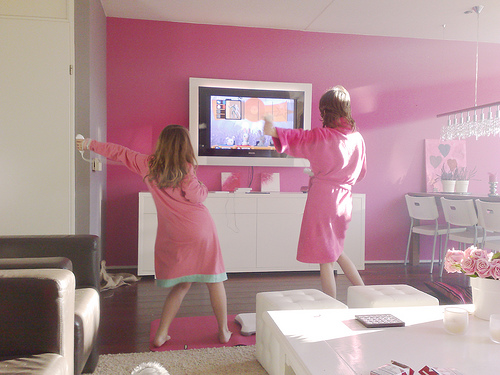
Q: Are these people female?
A: Yes, all the people are female.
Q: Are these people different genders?
A: No, all the people are female.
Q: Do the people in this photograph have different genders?
A: No, all the people are female.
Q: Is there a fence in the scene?
A: No, there are no fences.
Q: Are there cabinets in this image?
A: Yes, there is a cabinet.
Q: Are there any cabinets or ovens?
A: Yes, there is a cabinet.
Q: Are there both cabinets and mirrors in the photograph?
A: No, there is a cabinet but no mirrors.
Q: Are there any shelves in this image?
A: No, there are no shelves.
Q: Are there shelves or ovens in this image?
A: No, there are no shelves or ovens.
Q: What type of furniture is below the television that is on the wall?
A: The piece of furniture is a cabinet.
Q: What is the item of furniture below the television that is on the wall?
A: The piece of furniture is a cabinet.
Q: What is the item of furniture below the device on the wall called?
A: The piece of furniture is a cabinet.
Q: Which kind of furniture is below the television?
A: The piece of furniture is a cabinet.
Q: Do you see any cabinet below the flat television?
A: Yes, there is a cabinet below the television.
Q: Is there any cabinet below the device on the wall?
A: Yes, there is a cabinet below the television.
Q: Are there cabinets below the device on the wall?
A: Yes, there is a cabinet below the television.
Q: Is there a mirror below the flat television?
A: No, there is a cabinet below the TV.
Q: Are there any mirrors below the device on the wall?
A: No, there is a cabinet below the TV.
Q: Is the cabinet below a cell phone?
A: No, the cabinet is below a television.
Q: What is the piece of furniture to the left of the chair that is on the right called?
A: The piece of furniture is a cabinet.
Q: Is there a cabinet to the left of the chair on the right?
A: Yes, there is a cabinet to the left of the chair.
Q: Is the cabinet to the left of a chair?
A: Yes, the cabinet is to the left of a chair.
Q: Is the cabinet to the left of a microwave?
A: No, the cabinet is to the left of a chair.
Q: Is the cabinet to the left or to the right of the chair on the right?
A: The cabinet is to the left of the chair.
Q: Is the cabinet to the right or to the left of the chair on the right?
A: The cabinet is to the left of the chair.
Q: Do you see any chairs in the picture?
A: Yes, there is a chair.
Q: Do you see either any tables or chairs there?
A: Yes, there is a chair.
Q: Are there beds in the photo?
A: No, there are no beds.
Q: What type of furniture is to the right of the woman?
A: The piece of furniture is a chair.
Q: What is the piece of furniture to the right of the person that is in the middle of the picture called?
A: The piece of furniture is a chair.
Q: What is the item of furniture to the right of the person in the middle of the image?
A: The piece of furniture is a chair.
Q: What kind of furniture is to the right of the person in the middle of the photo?
A: The piece of furniture is a chair.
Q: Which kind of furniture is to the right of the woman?
A: The piece of furniture is a chair.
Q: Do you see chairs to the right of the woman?
A: Yes, there is a chair to the right of the woman.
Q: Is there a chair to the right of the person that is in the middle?
A: Yes, there is a chair to the right of the woman.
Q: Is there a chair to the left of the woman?
A: No, the chair is to the right of the woman.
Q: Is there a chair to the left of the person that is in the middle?
A: No, the chair is to the right of the woman.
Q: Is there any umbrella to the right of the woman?
A: No, there is a chair to the right of the woman.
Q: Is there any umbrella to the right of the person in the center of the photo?
A: No, there is a chair to the right of the woman.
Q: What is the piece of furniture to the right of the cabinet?
A: The piece of furniture is a chair.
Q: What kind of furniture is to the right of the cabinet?
A: The piece of furniture is a chair.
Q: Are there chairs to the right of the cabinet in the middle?
A: Yes, there is a chair to the right of the cabinet.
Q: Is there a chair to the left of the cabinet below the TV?
A: No, the chair is to the right of the cabinet.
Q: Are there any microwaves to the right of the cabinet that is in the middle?
A: No, there is a chair to the right of the cabinet.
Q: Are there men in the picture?
A: No, there are no men.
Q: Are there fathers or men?
A: No, there are no men or fathers.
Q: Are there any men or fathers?
A: No, there are no men or fathers.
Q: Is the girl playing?
A: Yes, the girl is playing.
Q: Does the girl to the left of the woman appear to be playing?
A: Yes, the girl is playing.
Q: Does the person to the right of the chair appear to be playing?
A: Yes, the girl is playing.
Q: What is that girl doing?
A: The girl is playing.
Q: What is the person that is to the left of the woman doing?
A: The girl is playing.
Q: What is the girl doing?
A: The girl is playing.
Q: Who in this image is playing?
A: The girl is playing.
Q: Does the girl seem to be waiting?
A: No, the girl is playing.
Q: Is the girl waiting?
A: No, the girl is playing.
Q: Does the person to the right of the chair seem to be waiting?
A: No, the girl is playing.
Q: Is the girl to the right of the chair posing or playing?
A: The girl is playing.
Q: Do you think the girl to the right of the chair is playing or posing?
A: The girl is playing.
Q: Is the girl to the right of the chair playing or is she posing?
A: The girl is playing.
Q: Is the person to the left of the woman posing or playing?
A: The girl is playing.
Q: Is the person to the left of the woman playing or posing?
A: The girl is playing.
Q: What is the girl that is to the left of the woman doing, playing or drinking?
A: The girl is playing.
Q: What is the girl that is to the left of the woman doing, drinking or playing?
A: The girl is playing.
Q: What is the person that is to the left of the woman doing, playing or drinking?
A: The girl is playing.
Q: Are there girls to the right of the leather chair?
A: Yes, there is a girl to the right of the chair.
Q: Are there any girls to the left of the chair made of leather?
A: No, the girl is to the right of the chair.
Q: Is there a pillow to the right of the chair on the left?
A: No, there is a girl to the right of the chair.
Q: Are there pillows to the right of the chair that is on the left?
A: No, there is a girl to the right of the chair.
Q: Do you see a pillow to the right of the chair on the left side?
A: No, there is a girl to the right of the chair.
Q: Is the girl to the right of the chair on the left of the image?
A: Yes, the girl is to the right of the chair.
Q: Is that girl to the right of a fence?
A: No, the girl is to the right of the chair.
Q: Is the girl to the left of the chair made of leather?
A: No, the girl is to the right of the chair.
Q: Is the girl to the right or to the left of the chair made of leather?
A: The girl is to the right of the chair.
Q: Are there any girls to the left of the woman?
A: Yes, there is a girl to the left of the woman.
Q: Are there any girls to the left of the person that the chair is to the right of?
A: Yes, there is a girl to the left of the woman.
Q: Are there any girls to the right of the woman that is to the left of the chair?
A: No, the girl is to the left of the woman.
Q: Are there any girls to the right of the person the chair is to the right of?
A: No, the girl is to the left of the woman.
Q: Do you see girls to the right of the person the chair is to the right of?
A: No, the girl is to the left of the woman.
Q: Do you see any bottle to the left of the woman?
A: No, there is a girl to the left of the woman.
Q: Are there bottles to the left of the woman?
A: No, there is a girl to the left of the woman.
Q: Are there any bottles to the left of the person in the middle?
A: No, there is a girl to the left of the woman.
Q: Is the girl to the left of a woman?
A: Yes, the girl is to the left of a woman.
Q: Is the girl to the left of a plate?
A: No, the girl is to the left of a woman.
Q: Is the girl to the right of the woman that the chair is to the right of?
A: No, the girl is to the left of the woman.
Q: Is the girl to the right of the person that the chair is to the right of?
A: No, the girl is to the left of the woman.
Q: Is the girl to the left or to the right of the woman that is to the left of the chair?
A: The girl is to the left of the woman.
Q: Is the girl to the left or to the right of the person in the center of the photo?
A: The girl is to the left of the woman.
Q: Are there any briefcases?
A: No, there are no briefcases.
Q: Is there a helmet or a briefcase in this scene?
A: No, there are no briefcases or helmets.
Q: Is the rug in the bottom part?
A: Yes, the rug is in the bottom of the image.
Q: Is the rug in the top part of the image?
A: No, the rug is in the bottom of the image.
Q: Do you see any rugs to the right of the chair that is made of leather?
A: Yes, there is a rug to the right of the chair.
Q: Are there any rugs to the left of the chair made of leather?
A: No, the rug is to the right of the chair.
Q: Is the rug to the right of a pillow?
A: No, the rug is to the right of a chair.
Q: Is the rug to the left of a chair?
A: No, the rug is to the right of a chair.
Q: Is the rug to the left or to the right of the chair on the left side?
A: The rug is to the right of the chair.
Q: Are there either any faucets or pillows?
A: No, there are no pillows or faucets.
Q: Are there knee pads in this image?
A: No, there are no knee pads.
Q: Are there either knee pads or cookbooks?
A: No, there are no knee pads or cookbooks.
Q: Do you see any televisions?
A: Yes, there is a television.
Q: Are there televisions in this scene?
A: Yes, there is a television.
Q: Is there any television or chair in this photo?
A: Yes, there is a television.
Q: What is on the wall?
A: The television is on the wall.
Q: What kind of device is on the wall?
A: The device is a television.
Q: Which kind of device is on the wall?
A: The device is a television.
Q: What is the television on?
A: The television is on the wall.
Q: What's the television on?
A: The television is on the wall.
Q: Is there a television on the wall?
A: Yes, there is a television on the wall.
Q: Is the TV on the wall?
A: Yes, the TV is on the wall.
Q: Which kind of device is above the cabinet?
A: The device is a television.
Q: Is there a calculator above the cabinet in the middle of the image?
A: No, there is a television above the cabinet.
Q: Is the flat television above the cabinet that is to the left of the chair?
A: Yes, the television is above the cabinet.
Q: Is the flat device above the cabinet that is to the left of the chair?
A: Yes, the television is above the cabinet.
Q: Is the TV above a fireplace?
A: No, the TV is above the cabinet.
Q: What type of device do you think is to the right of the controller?
A: The device is a television.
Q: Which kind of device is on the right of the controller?
A: The device is a television.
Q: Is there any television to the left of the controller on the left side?
A: No, the television is to the right of the controller.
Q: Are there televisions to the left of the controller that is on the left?
A: No, the television is to the right of the controller.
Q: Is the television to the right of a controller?
A: Yes, the television is to the right of a controller.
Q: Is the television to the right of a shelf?
A: No, the television is to the right of a controller.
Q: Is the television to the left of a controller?
A: No, the television is to the right of a controller.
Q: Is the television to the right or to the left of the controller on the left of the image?
A: The television is to the right of the controller.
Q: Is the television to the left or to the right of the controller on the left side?
A: The television is to the right of the controller.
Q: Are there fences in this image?
A: No, there are no fences.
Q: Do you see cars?
A: No, there are no cars.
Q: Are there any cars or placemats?
A: No, there are no cars or placemats.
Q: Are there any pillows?
A: No, there are no pillows.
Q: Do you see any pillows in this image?
A: No, there are no pillows.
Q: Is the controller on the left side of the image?
A: Yes, the controller is on the left of the image.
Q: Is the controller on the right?
A: No, the controller is on the left of the image.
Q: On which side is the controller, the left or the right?
A: The controller is on the left of the image.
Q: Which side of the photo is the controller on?
A: The controller is on the left of the image.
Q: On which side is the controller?
A: The controller is on the left of the image.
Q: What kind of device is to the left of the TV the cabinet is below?
A: The device is a controller.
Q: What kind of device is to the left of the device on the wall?
A: The device is a controller.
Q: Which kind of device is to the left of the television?
A: The device is a controller.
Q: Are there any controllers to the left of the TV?
A: Yes, there is a controller to the left of the TV.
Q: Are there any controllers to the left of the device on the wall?
A: Yes, there is a controller to the left of the TV.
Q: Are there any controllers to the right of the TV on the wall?
A: No, the controller is to the left of the TV.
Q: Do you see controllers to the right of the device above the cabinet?
A: No, the controller is to the left of the TV.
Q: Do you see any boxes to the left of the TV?
A: No, there is a controller to the left of the TV.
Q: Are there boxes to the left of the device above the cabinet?
A: No, there is a controller to the left of the TV.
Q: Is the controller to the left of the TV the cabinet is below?
A: Yes, the controller is to the left of the TV.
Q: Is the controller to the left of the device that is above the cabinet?
A: Yes, the controller is to the left of the TV.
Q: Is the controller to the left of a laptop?
A: No, the controller is to the left of the TV.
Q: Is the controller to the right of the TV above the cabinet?
A: No, the controller is to the left of the television.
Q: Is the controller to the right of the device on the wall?
A: No, the controller is to the left of the television.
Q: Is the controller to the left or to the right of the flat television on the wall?
A: The controller is to the left of the TV.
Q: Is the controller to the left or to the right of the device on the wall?
A: The controller is to the left of the TV.